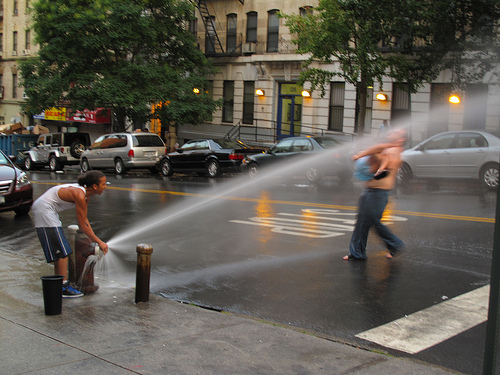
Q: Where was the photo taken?
A: It was taken at the sidewalk.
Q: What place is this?
A: It is a sidewalk.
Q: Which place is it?
A: It is a sidewalk.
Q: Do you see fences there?
A: No, there are no fences.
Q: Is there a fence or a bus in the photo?
A: No, there are no fences or buses.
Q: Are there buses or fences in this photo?
A: No, there are no fences or buses.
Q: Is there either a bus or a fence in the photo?
A: No, there are no fences or buses.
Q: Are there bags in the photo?
A: No, there are no bags.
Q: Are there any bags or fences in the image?
A: No, there are no bags or fences.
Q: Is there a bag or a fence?
A: No, there are no bags or fences.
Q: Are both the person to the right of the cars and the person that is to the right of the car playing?
A: Yes, both the person and the person are playing.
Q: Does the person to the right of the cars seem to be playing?
A: Yes, the person is playing.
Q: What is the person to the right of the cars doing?
A: The person is playing.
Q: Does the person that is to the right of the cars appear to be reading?
A: No, the person is playing.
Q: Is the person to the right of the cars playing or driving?
A: The person is playing.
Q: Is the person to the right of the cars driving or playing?
A: The person is playing.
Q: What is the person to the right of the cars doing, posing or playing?
A: The person is playing.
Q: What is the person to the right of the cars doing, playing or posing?
A: The person is playing.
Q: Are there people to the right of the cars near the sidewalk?
A: Yes, there is a person to the right of the cars.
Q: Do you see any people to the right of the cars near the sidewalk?
A: Yes, there is a person to the right of the cars.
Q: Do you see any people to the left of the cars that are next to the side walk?
A: No, the person is to the right of the cars.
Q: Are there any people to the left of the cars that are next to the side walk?
A: No, the person is to the right of the cars.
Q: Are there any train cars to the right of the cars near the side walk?
A: No, there is a person to the right of the cars.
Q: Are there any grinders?
A: No, there are no grinders.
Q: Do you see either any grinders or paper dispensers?
A: No, there are no grinders or paper dispensers.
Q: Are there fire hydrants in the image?
A: Yes, there is a fire hydrant.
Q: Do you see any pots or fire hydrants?
A: Yes, there is a fire hydrant.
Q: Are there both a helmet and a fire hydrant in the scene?
A: No, there is a fire hydrant but no helmets.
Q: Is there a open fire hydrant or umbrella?
A: Yes, there is an open fire hydrant.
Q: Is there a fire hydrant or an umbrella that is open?
A: Yes, the fire hydrant is open.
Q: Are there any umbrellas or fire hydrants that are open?
A: Yes, the fire hydrant is open.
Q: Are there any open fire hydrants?
A: Yes, there is an open fire hydrant.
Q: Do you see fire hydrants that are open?
A: Yes, there is a fire hydrant that is open.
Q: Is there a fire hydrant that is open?
A: Yes, there is a fire hydrant that is open.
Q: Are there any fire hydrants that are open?
A: Yes, there is a fire hydrant that is open.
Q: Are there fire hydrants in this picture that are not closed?
A: Yes, there is a open fire hydrant.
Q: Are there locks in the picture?
A: No, there are no locks.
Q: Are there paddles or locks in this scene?
A: No, there are no locks or paddles.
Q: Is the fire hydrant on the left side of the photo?
A: Yes, the fire hydrant is on the left of the image.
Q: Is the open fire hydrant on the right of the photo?
A: No, the hydrant is on the left of the image.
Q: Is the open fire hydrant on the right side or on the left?
A: The fire hydrant is on the left of the image.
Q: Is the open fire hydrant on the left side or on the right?
A: The fire hydrant is on the left of the image.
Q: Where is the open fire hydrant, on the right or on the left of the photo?
A: The fire hydrant is on the left of the image.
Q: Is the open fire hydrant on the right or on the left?
A: The fire hydrant is on the left of the image.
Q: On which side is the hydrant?
A: The hydrant is on the left of the image.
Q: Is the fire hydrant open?
A: Yes, the fire hydrant is open.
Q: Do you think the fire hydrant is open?
A: Yes, the fire hydrant is open.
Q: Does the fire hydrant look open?
A: Yes, the fire hydrant is open.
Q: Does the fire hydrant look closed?
A: No, the fire hydrant is open.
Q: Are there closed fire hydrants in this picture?
A: No, there is a fire hydrant but it is open.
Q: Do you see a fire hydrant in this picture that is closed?
A: No, there is a fire hydrant but it is open.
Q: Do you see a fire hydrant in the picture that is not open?
A: No, there is a fire hydrant but it is open.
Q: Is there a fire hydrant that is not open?
A: No, there is a fire hydrant but it is open.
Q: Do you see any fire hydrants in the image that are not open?
A: No, there is a fire hydrant but it is open.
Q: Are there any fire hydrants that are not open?
A: No, there is a fire hydrant but it is open.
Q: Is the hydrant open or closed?
A: The hydrant is open.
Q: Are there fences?
A: No, there are no fences.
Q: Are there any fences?
A: No, there are no fences.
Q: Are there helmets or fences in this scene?
A: No, there are no fences or helmets.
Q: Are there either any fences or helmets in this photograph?
A: No, there are no fences or helmets.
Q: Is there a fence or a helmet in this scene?
A: No, there are no fences or helmets.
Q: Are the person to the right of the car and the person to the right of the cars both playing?
A: Yes, both the person and the person are playing.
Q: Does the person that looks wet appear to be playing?
A: Yes, the person is playing.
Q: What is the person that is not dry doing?
A: The person is playing.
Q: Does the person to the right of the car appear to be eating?
A: No, the person is playing.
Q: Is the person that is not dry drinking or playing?
A: The person is playing.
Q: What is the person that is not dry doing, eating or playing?
A: The person is playing.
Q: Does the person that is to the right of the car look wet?
A: Yes, the person is wet.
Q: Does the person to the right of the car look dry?
A: No, the person is wet.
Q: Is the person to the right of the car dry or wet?
A: The person is wet.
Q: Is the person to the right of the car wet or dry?
A: The person is wet.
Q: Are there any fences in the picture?
A: No, there are no fences.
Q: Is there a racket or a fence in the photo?
A: No, there are no fences or rackets.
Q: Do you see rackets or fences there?
A: No, there are no fences or rackets.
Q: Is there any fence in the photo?
A: No, there are no fences.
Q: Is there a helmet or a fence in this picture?
A: No, there are no fences or helmets.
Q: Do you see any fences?
A: No, there are no fences.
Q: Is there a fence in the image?
A: No, there are no fences.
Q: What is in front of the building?
A: The tree is in front of the building.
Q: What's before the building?
A: The tree is in front of the building.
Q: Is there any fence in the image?
A: No, there are no fences.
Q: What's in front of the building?
A: The tree is in front of the building.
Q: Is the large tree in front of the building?
A: Yes, the tree is in front of the building.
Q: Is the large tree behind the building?
A: No, the tree is in front of the building.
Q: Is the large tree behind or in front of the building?
A: The tree is in front of the building.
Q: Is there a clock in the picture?
A: No, there are no clocks.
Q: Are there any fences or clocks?
A: No, there are no clocks or fences.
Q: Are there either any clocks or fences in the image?
A: No, there are no clocks or fences.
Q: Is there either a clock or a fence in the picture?
A: No, there are no clocks or fences.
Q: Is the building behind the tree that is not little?
A: Yes, the building is behind the tree.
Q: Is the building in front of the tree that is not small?
A: No, the building is behind the tree.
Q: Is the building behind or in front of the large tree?
A: The building is behind the tree.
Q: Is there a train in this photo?
A: No, there are no trains.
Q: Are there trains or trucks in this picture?
A: No, there are no trains or trucks.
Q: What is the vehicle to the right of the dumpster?
A: The vehicle is a car.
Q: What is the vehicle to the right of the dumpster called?
A: The vehicle is a car.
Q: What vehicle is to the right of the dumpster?
A: The vehicle is a car.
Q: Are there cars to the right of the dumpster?
A: Yes, there is a car to the right of the dumpster.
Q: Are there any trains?
A: No, there are no trains.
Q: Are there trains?
A: No, there are no trains.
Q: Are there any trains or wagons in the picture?
A: No, there are no trains or wagons.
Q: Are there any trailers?
A: No, there are no trailers.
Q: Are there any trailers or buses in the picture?
A: No, there are no trailers or buses.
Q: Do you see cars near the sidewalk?
A: Yes, there are cars near the sidewalk.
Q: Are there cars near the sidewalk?
A: Yes, there are cars near the sidewalk.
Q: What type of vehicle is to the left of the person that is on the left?
A: The vehicles are cars.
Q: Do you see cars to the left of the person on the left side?
A: Yes, there are cars to the left of the person.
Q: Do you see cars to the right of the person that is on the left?
A: No, the cars are to the left of the person.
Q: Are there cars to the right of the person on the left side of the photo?
A: No, the cars are to the left of the person.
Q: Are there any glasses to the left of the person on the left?
A: No, there are cars to the left of the person.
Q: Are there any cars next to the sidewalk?
A: Yes, there are cars next to the sidewalk.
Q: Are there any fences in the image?
A: No, there are no fences.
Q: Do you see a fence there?
A: No, there are no fences.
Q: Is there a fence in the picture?
A: No, there are no fences.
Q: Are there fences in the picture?
A: No, there are no fences.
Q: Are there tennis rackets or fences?
A: No, there are no fences or tennis rackets.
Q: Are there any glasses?
A: No, there are no glasses.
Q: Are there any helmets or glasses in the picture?
A: No, there are no glasses or helmets.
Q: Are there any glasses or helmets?
A: No, there are no glasses or helmets.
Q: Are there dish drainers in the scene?
A: No, there are no dish drainers.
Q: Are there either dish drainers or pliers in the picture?
A: No, there are no dish drainers or pliers.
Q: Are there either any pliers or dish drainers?
A: No, there are no dish drainers or pliers.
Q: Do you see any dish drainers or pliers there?
A: No, there are no dish drainers or pliers.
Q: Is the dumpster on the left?
A: Yes, the dumpster is on the left of the image.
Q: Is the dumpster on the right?
A: No, the dumpster is on the left of the image.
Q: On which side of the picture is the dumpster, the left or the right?
A: The dumpster is on the left of the image.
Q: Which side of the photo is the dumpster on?
A: The dumpster is on the left of the image.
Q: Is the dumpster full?
A: Yes, the dumpster is full.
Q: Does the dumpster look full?
A: Yes, the dumpster is full.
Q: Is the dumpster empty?
A: No, the dumpster is full.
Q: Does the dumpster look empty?
A: No, the dumpster is full.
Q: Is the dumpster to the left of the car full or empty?
A: The dumpster is full.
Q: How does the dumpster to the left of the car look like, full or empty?
A: The dumpster is full.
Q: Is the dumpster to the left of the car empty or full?
A: The dumpster is full.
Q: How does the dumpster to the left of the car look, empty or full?
A: The dumpster is full.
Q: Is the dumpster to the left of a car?
A: Yes, the dumpster is to the left of a car.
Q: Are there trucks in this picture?
A: No, there are no trucks.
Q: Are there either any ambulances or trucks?
A: No, there are no trucks or ambulances.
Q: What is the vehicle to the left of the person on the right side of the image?
A: The vehicle is a car.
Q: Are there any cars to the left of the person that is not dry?
A: Yes, there is a car to the left of the person.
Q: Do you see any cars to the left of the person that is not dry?
A: Yes, there is a car to the left of the person.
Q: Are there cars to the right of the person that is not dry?
A: No, the car is to the left of the person.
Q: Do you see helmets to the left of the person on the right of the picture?
A: No, there is a car to the left of the person.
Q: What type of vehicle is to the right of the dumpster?
A: The vehicle is a car.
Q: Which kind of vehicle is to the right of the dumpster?
A: The vehicle is a car.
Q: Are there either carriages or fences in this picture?
A: No, there are no fences or carriages.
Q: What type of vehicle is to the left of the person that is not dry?
A: The vehicle is a car.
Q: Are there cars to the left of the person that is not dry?
A: Yes, there is a car to the left of the person.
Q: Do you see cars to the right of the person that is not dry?
A: No, the car is to the left of the person.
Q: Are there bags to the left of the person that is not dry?
A: No, there is a car to the left of the person.